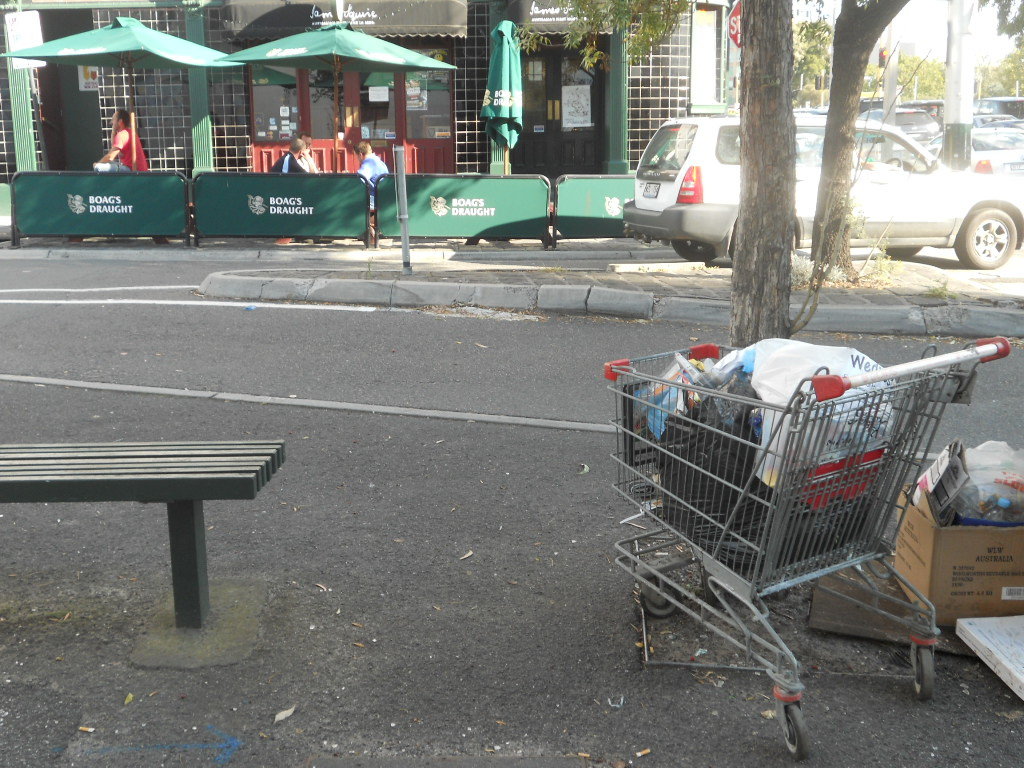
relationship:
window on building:
[134, 102, 189, 131] [4, 0, 731, 250]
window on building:
[95, 12, 193, 175] [4, 0, 731, 250]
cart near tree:
[571, 270, 1021, 758] [506, 3, 802, 349]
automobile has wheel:
[614, 107, 1023, 275] [962, 217, 1023, 268]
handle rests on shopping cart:
[783, 334, 1021, 398] [596, 376, 972, 705]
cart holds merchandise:
[572, 308, 1009, 762] [658, 361, 888, 502]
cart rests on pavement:
[572, 308, 1009, 762] [34, 329, 990, 740]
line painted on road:
[247, 346, 685, 471] [89, 290, 659, 518]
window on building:
[647, 67, 692, 96] [4, 0, 731, 250]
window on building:
[206, 70, 254, 173] [4, 0, 731, 250]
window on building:
[620, 32, 656, 90] [4, 0, 731, 250]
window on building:
[207, 70, 296, 176] [4, 0, 731, 250]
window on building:
[388, 40, 482, 174] [4, 0, 731, 250]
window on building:
[459, 109, 483, 164] [4, 0, 731, 250]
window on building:
[632, 3, 697, 176] [4, 0, 731, 250]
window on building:
[209, 66, 303, 170] [4, 0, 731, 250]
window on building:
[154, 58, 193, 93] [4, 0, 731, 250]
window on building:
[151, 92, 187, 141] [4, 0, 731, 250]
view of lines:
[6, 346, 691, 481] [329, 368, 450, 446]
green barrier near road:
[6, 154, 661, 246] [11, 300, 1019, 740]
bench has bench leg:
[0, 396, 321, 625] [129, 509, 244, 658]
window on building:
[453, 51, 479, 89] [4, 0, 731, 250]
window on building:
[211, 84, 243, 138] [4, 0, 731, 250]